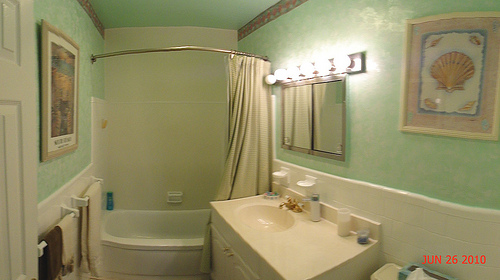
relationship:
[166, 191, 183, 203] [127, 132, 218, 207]
holder on wall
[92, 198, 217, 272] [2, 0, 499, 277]
tub in bathroom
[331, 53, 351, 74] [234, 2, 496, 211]
light on wall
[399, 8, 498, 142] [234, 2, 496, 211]
picture hanging on wall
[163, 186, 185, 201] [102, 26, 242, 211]
dish hanging on wall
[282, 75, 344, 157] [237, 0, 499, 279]
mirror on wall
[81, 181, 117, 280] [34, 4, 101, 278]
towel hanging on wall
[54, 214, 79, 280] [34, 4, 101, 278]
towel hanging on wall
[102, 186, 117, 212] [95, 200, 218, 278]
blue bottle on corner of tub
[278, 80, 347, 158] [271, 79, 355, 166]
reflection in mirror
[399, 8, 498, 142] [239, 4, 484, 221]
picture on wall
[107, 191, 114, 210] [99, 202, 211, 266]
blue bottle in tub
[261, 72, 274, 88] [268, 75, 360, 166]
light bulb above mirror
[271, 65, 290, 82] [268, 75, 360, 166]
light bulb above mirror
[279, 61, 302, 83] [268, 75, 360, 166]
light bulb above mirror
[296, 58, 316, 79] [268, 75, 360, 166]
light bulb above mirror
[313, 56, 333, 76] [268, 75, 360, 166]
light bulb above mirror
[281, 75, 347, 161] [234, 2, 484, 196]
mirror on wall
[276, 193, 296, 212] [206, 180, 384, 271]
faucet on sink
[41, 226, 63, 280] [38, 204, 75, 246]
bowl towel hanging on rod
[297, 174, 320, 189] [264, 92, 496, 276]
soap dish hanging on wall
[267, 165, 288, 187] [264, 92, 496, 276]
soap dish hanging on wall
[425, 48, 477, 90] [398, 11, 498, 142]
sea shell on picture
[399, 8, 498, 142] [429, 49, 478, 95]
picture of shell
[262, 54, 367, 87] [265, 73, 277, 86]
row of light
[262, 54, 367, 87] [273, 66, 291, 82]
row of light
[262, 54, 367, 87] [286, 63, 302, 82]
row of light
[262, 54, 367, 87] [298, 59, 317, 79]
row of light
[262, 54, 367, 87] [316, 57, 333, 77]
row of light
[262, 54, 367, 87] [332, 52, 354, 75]
row of light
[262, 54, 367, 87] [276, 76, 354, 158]
row above mirror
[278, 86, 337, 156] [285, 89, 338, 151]
reflection in mirror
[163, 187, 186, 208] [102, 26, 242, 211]
soap dish on wall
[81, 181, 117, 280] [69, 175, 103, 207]
towel hanging on rod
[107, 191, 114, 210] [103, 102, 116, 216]
blue bottle on corner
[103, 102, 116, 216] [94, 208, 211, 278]
corner of tub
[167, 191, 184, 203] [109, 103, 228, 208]
holder on wall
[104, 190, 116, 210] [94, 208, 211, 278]
shampoo on tub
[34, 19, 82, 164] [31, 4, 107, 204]
picture on wall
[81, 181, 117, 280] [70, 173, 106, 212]
towel on holder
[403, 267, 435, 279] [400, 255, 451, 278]
tissue in box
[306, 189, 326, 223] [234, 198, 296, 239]
bottle on sink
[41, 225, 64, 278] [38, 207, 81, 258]
bowl towel on bar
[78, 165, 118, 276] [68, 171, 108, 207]
towel on bar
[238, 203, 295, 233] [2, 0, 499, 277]
sink in bathroom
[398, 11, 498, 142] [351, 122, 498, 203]
picture on wall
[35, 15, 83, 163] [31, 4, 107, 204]
picture on wall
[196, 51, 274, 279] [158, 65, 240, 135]
curtain in bathroom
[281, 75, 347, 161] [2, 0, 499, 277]
mirror in bathroom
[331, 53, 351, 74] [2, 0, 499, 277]
light in bathroom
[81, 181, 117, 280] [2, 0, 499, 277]
towel in bathroom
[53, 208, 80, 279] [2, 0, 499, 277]
towel in bathroom